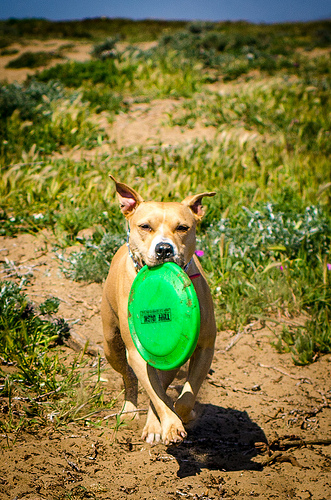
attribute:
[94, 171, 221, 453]
dog — motion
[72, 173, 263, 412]
dog — tan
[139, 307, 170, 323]
writing — black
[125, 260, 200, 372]
frisbee — green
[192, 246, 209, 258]
flower —  purple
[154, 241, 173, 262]
nose — black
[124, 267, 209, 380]
frisbee — mouth